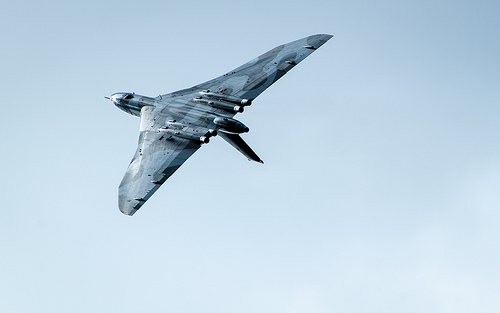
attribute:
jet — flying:
[105, 32, 335, 214]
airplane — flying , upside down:
[104, 32, 334, 215]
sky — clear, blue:
[1, 1, 484, 310]